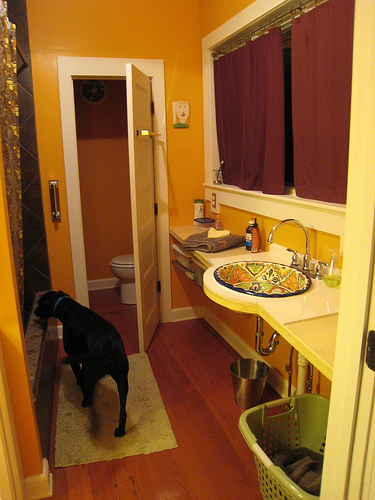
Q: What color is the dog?
A: Black.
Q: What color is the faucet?
A: Silver.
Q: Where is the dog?
A: On the bath mat.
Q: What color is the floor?
A: Brown.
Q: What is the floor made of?
A: Wood.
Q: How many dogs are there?
A: One.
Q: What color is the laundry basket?
A: Green.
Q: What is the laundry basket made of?
A: Plastic.